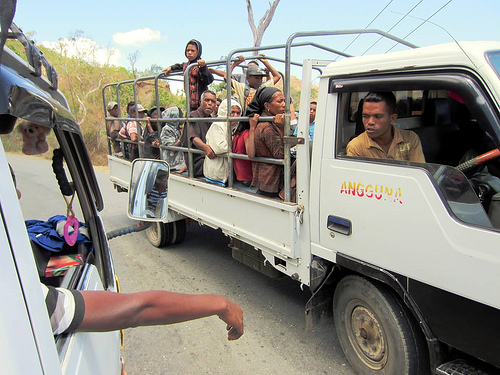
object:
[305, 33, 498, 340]
truck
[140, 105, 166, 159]
people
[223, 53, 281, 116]
boy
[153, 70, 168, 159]
bar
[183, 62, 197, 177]
bar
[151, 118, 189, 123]
bar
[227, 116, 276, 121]
bar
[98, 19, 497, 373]
truck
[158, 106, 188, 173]
people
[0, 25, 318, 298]
back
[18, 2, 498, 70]
sky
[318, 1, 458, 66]
three wires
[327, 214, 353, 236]
door handle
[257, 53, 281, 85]
arms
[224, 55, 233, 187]
bar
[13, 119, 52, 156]
bear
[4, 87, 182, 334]
truck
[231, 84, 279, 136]
scarf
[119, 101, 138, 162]
person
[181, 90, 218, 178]
person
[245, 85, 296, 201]
person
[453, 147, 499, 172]
steering wheel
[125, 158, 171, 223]
mirror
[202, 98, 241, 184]
person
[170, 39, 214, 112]
jacket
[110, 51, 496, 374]
truck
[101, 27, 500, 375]
vehicle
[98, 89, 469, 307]
truck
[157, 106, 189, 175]
passengers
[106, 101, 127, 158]
passengers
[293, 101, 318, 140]
boy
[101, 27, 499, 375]
back truck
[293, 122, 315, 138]
blue shirt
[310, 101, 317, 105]
black hair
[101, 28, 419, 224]
ribs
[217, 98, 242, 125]
hood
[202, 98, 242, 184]
jacket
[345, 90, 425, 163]
driver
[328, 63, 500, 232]
window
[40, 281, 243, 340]
person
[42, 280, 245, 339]
arm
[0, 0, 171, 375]
vehicle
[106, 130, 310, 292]
truck bed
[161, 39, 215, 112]
boy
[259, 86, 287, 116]
head